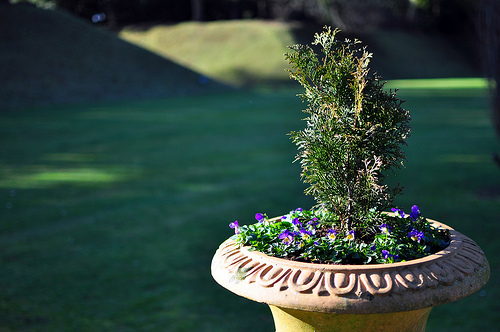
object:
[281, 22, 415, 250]
plant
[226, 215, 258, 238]
plant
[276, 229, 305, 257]
plant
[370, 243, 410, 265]
plant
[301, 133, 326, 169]
leaves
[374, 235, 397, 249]
leaves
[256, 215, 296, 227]
leaves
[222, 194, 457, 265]
flowers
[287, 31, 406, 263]
shrub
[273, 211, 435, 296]
soil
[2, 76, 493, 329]
lawn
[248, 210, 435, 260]
center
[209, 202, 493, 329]
plant pot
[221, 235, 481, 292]
pattern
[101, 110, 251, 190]
grass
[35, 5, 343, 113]
hill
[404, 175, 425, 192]
ground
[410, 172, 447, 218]
ground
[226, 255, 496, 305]
design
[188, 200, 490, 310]
planter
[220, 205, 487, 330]
pot holder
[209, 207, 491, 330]
flower pot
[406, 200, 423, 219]
pansy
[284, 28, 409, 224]
bush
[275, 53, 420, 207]
tree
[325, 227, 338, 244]
flower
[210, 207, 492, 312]
base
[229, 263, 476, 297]
design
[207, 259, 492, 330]
holder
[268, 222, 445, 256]
pansy